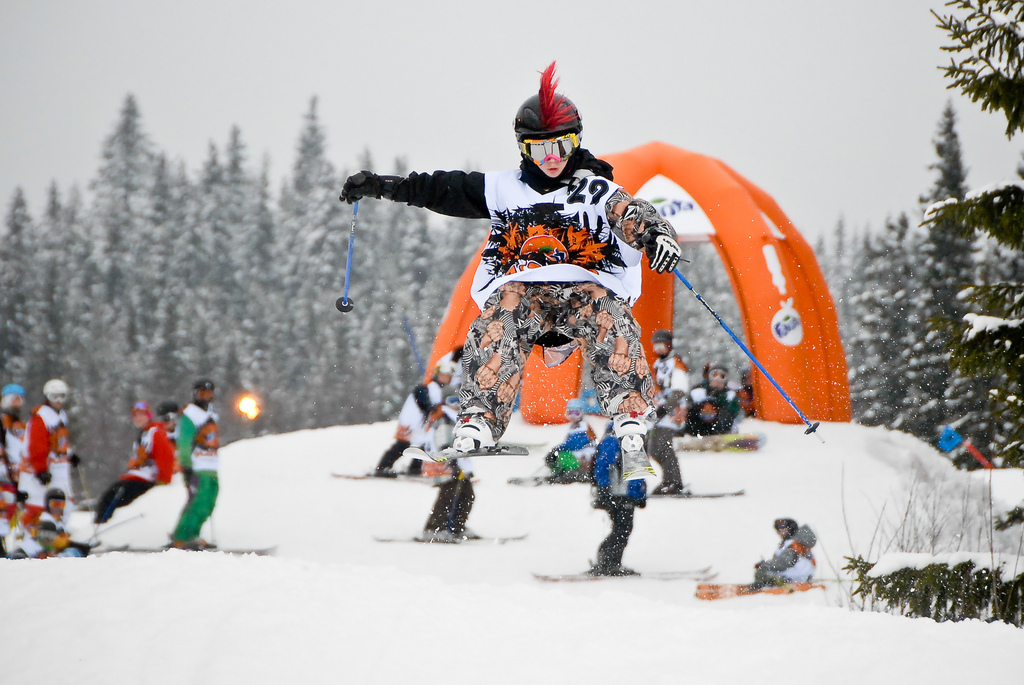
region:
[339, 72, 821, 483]
a person wearing skis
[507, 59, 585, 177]
a person wearing a mohawk helmet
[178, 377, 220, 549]
a person dressed in white and green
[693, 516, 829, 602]
a person sitting on the snow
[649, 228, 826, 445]
a hand holding a blue ski pole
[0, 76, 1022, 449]
snow covered evergreen trees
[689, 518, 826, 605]
a person with orange skis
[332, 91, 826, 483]
a skier that is midair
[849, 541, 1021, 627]
a snow covered tree branch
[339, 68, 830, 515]
Boy on skis in mid-air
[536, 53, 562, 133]
Feather on the boy's helmet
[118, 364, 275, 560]
Skier in green snowpants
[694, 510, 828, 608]
Skier sitting in the snow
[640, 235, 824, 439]
Ski pole in boy's hand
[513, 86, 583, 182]
Helmet and goggles on boy's head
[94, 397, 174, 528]
Person sitting in the snow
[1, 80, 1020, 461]
Snow-covered trees in the background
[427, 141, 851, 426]
Orange inflatable object in the snow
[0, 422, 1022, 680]
Snow covered ground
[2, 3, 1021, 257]
light in daytime sky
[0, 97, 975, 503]
snow on evergreen trees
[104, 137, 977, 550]
orange dome on slope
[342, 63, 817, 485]
front of jumping skier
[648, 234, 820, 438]
gloved hand holding pole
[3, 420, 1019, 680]
snow cover on ground surface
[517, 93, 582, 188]
helmet on skier's head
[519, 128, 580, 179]
goggles on skier's face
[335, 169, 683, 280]
extended arms of skier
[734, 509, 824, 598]
a person is sitting down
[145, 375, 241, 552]
A person on some snow.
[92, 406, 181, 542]
A person on some snow.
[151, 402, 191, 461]
A person on some snow.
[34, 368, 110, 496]
A person on some snow.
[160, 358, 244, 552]
A person on some snow.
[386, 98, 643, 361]
A person on some snow.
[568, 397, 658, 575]
A person on some snow.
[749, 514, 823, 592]
A person on some snow.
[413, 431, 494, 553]
A person on some snow.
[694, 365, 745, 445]
A person on some snow.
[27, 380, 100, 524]
A person on some snow.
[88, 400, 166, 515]
A person on some snow.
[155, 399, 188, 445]
A person on some snow.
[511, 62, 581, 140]
a black helmet with a red mohawk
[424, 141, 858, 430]
an orange inflated shelter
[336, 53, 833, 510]
a person wearing a white, black, and orange shirt.